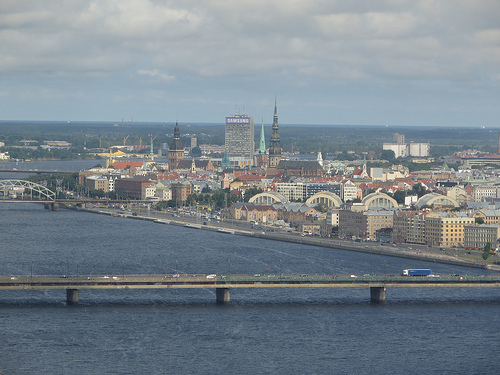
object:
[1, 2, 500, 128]
sky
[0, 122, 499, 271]
land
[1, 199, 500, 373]
water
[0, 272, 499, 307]
bridge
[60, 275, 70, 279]
cars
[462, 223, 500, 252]
buildings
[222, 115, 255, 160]
building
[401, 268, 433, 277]
truck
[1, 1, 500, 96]
clouds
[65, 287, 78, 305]
pillar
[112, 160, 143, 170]
roof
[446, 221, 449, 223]
window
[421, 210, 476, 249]
building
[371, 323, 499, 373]
ripples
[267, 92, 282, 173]
tower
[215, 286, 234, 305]
pillar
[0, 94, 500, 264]
city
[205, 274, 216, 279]
car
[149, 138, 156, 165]
building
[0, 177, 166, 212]
bridge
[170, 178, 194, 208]
houses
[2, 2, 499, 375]
picture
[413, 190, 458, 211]
archways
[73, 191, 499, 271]
street